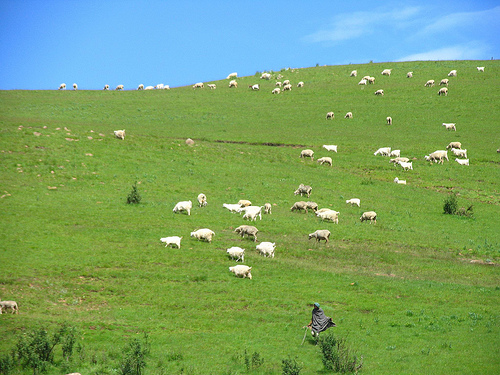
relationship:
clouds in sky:
[316, 8, 478, 40] [252, 6, 290, 28]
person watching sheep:
[294, 299, 339, 340] [150, 185, 284, 281]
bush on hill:
[440, 190, 476, 222] [177, 100, 221, 126]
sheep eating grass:
[150, 185, 284, 281] [285, 220, 302, 232]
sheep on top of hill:
[150, 185, 284, 281] [177, 100, 221, 126]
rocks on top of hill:
[12, 116, 52, 143] [177, 100, 221, 126]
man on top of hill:
[294, 299, 339, 340] [177, 100, 221, 126]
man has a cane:
[294, 299, 339, 340] [299, 323, 309, 346]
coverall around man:
[306, 311, 339, 330] [294, 299, 339, 340]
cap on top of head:
[311, 300, 321, 308] [310, 301, 322, 313]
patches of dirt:
[19, 122, 80, 145] [31, 127, 43, 140]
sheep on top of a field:
[150, 185, 284, 281] [219, 104, 286, 142]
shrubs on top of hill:
[10, 319, 158, 365] [177, 100, 221, 126]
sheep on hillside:
[150, 185, 284, 281] [407, 46, 453, 66]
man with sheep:
[294, 299, 339, 340] [150, 185, 284, 281]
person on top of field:
[294, 299, 339, 340] [219, 104, 286, 142]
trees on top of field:
[10, 319, 158, 365] [219, 104, 286, 142]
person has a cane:
[294, 299, 339, 340] [299, 323, 309, 346]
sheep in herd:
[190, 218, 293, 276] [150, 185, 284, 281]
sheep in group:
[161, 184, 308, 289] [150, 185, 284, 281]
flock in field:
[150, 185, 284, 281] [110, 89, 477, 312]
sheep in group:
[150, 185, 284, 281] [150, 185, 284, 281]